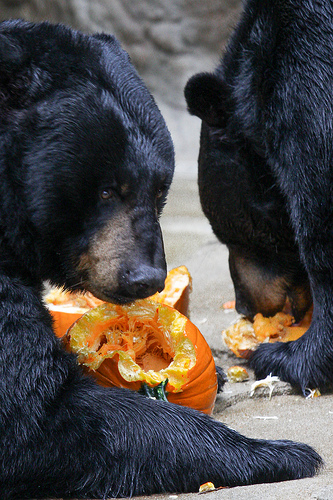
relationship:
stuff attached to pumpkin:
[103, 318, 160, 351] [60, 297, 213, 412]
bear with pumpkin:
[10, 38, 237, 332] [71, 306, 283, 462]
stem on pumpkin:
[127, 375, 196, 408] [77, 303, 254, 437]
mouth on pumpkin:
[242, 285, 304, 315] [227, 310, 309, 348]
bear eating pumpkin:
[184, 0, 331, 396] [222, 299, 321, 399]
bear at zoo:
[184, 0, 331, 396] [0, 1, 331, 498]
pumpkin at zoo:
[222, 299, 321, 399] [0, 1, 331, 498]